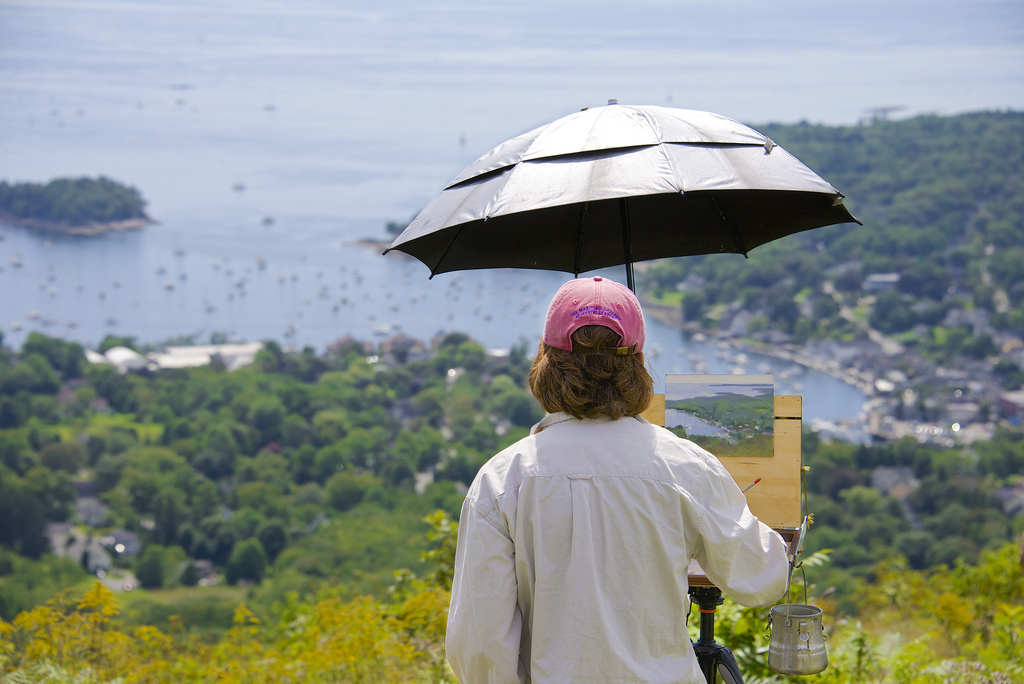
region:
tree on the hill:
[235, 547, 274, 566]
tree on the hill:
[332, 476, 374, 503]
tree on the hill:
[336, 389, 413, 440]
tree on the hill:
[106, 418, 138, 457]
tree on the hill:
[14, 341, 57, 398]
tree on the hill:
[242, 345, 300, 372]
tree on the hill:
[396, 429, 474, 486]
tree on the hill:
[459, 394, 502, 417]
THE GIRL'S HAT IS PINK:
[533, 261, 655, 356]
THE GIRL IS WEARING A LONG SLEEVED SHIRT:
[409, 394, 789, 674]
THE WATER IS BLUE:
[1, 0, 1019, 444]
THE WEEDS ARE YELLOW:
[8, 487, 1015, 678]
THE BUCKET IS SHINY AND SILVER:
[740, 535, 861, 678]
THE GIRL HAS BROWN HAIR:
[494, 276, 663, 442]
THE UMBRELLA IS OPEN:
[387, 83, 885, 352]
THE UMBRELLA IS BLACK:
[400, 76, 859, 370]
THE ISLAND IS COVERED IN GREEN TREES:
[0, 159, 165, 252]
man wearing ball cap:
[525, 268, 643, 367]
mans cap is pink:
[531, 271, 650, 366]